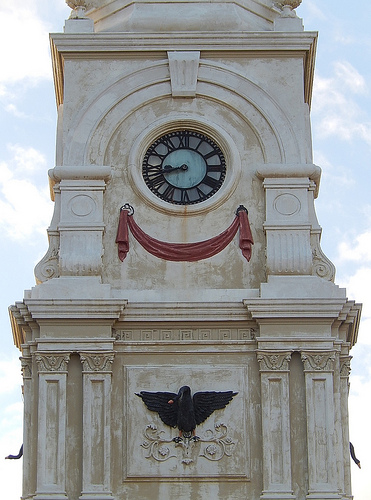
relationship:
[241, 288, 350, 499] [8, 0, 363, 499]
pillar on monument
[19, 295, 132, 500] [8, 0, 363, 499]
pillar on monument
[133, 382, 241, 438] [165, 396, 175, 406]
swan has beak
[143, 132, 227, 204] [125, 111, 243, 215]
face of clock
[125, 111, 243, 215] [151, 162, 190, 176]
clock has hour hand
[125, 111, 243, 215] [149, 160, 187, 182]
clock has minute hand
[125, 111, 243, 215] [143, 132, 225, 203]
clock has roman numerals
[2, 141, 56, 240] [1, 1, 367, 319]
clouds in sky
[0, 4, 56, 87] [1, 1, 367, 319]
clouds in sky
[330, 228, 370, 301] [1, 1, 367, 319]
clouds in sky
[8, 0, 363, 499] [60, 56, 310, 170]
monument has arch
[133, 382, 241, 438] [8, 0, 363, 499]
eagle on monument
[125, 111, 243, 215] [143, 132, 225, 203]
clock has roman numbers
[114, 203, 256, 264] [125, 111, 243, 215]
ribbon under clock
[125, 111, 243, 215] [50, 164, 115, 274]
clock has column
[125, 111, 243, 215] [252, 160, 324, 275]
clock has column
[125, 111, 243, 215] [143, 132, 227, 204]
clock has face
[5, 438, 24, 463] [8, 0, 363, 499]
bird hanging from monument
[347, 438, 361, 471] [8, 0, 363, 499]
bird hanging from monument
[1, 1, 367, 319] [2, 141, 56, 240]
sky has clouds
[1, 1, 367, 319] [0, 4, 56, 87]
sky has clouds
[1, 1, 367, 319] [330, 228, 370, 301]
sky has clouds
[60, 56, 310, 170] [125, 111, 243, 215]
arch over clock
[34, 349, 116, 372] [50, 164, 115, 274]
design on column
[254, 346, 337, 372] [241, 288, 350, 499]
design on column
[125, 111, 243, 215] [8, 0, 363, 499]
clock on monument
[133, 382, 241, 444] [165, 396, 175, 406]
swan has beak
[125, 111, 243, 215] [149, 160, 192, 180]
clock has hands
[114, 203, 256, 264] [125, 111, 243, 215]
object under clock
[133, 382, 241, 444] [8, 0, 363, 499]
swan on monument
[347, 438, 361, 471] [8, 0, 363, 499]
bird on monument